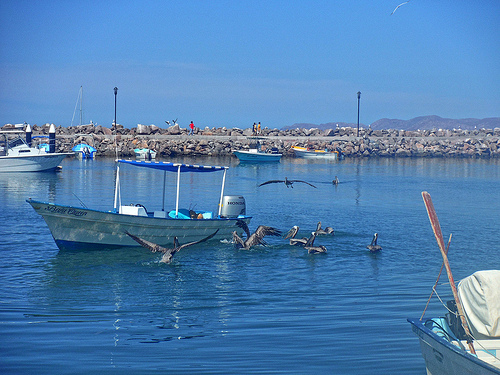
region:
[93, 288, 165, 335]
the water is calm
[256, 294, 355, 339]
the water is calm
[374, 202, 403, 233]
the water is calm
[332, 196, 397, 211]
the water is calm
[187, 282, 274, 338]
the water is calm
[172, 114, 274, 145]
people walking at the dock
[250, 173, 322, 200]
long span bird flying over water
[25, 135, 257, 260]
blue silver boat in water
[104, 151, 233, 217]
striped blued canopy on top of boat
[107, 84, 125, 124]
tall street lamp on black pole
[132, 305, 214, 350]
dark line ripples in water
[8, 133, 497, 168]
short rock wall barrier bordering water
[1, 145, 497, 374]
large blue body of water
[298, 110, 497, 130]
brown mountain formations in horizon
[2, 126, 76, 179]
white boat in body of water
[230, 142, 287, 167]
blue boat in body of water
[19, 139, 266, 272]
a boat in the water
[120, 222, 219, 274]
a bird with wings spread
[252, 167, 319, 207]
a bird coming in for a landing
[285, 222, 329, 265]
two birds floating on the water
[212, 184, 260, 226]
the outboard engine of a small boat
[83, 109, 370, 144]
people gathered near the shoreline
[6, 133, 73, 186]
a boat at a dock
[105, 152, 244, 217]
an awning over a small boat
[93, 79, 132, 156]
a light post on a pier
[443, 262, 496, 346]
a boat motor with a cover over it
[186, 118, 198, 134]
person wearing a red shirt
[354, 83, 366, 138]
lamp on a pole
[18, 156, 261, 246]
boat with a blue canopy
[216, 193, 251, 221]
Honda boat motor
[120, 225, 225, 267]
pelican with its wings spread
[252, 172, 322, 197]
pelican flying in the air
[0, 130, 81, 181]
white boat on the water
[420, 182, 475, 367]
wooden oar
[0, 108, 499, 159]
rocky path near the water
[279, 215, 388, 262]
pelicans in the water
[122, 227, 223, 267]
A bird diving into the ocean.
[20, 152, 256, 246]
A boat with no one on it.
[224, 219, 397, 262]
A group of birds in the ocean.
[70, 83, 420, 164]
A rocky beach with people on it.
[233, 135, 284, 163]
A boat in the background.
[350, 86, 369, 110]
A light for boats at night.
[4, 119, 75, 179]
A boat in the back ground with two things sticking up.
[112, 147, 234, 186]
A roof on a boat for the rain.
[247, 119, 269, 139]
Two people in floating vests.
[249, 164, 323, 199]
A bird in mid flight.